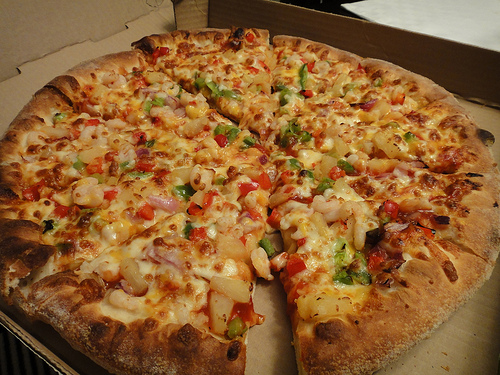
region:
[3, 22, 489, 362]
pizza in a box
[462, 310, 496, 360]
carboard of a pizza box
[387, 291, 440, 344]
crust of a pizza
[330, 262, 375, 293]
green peppers on a pizza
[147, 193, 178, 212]
onion on a pizza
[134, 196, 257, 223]
tomato on a pizza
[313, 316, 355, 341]
burnt bubble on crust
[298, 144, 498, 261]
triangle of a pizza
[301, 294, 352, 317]
herbs on a pizza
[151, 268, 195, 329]
melted cheese on pizza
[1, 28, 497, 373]
Pizza with lots of toppings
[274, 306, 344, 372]
edge of crust near missing piece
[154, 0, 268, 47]
top corner of the pizza box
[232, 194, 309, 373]
missing piece of pizza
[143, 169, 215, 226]
peppers, onions and tomatos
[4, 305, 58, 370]
edge of the pizza box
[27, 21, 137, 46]
fold between top and bottom of the pizza box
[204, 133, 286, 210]
middle of the pizza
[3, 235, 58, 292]
burnt crust of pizza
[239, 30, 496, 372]
right half of the pizza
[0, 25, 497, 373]
Delicious combination pizza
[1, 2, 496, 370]
Cardboard box for pizza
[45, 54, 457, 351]
Bell peppers in topping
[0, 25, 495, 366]
Crisp and toasted pizza crust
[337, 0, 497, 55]
Napkin sitting beside pizza box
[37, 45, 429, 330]
Pineapple chunks as topping on pizza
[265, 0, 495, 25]
Black table beside pizza box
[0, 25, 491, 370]
Garlic seasoning on toasted crust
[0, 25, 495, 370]
Pizza slices in cardboard box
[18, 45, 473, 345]
Melted cheese as pizza topping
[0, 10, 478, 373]
Cooked pizza cut into slices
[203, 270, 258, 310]
Chunks of pineapple on pizza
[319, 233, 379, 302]
Green peppers on pizza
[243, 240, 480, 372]
Golden crust on pizza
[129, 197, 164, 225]
Chunks of tomato on pizza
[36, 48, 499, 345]
Melted cheese on pizza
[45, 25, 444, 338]
Tomato sauce under cheese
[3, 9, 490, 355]
Large cardboard pizza box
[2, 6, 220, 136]
Fold at edge of pizza box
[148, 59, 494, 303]
Slices cut into pizza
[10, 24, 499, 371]
Large sliced pizza.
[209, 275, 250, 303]
A piece of onion on the pizza.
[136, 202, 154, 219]
A piece of tomato on the pizza.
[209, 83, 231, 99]
A piece of green bell pepper.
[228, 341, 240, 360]
Burnt piece on pizza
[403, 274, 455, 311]
Piece of the pizza crust.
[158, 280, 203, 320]
Piece of cheese topping.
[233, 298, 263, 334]
Part of the tomato sauce.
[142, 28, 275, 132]
A slice of the pizza.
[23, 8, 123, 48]
Part of the carboard box.